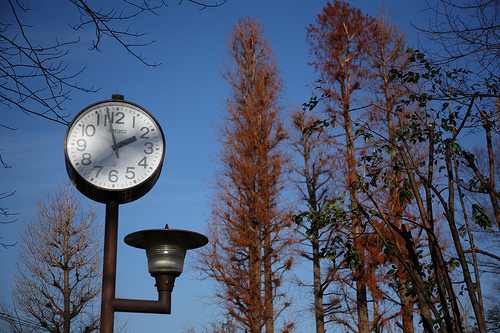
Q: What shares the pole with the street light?
A: Clock.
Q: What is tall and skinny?
A: Trees.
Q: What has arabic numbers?
A: Clock.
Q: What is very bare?
A: Tree.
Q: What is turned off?
A: Light.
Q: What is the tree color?
A: Green.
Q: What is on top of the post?
A: Clock.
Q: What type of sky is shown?
A: Clear blue.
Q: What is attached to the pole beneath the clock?
A: Lamp.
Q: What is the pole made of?
A: Metal.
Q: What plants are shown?
A: Trees.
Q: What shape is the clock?
A: Circle.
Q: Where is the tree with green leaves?
A: Right side.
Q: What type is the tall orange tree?
A: Pine tree.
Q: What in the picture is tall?
A: The tree.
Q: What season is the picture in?
A: Autumn.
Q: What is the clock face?
A: White.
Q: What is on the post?
A: A clock.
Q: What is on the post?
A: A light.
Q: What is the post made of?
A: Metal.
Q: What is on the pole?
A: A street light.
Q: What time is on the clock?
A: 1:58 PM.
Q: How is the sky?
A: Clear.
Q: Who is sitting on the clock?
A: No one.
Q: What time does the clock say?
A: 1:57.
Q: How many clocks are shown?
A: One.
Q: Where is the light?
A: On the bottom.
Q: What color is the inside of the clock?
A: White.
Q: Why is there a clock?
A: So people can tell time.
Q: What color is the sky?
A: Blue.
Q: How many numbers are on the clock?
A: Twelve.